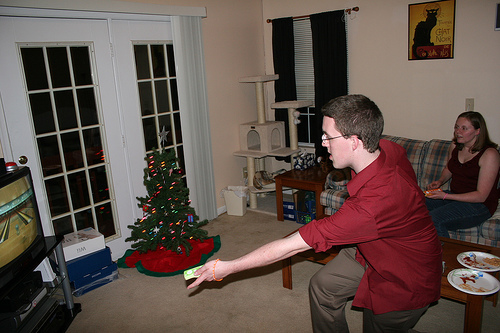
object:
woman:
[420, 111, 499, 240]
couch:
[318, 133, 499, 249]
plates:
[455, 250, 499, 272]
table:
[278, 215, 499, 333]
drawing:
[404, 0, 456, 61]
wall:
[261, 0, 498, 194]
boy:
[185, 93, 442, 332]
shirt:
[296, 138, 442, 315]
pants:
[307, 245, 437, 332]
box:
[50, 226, 107, 264]